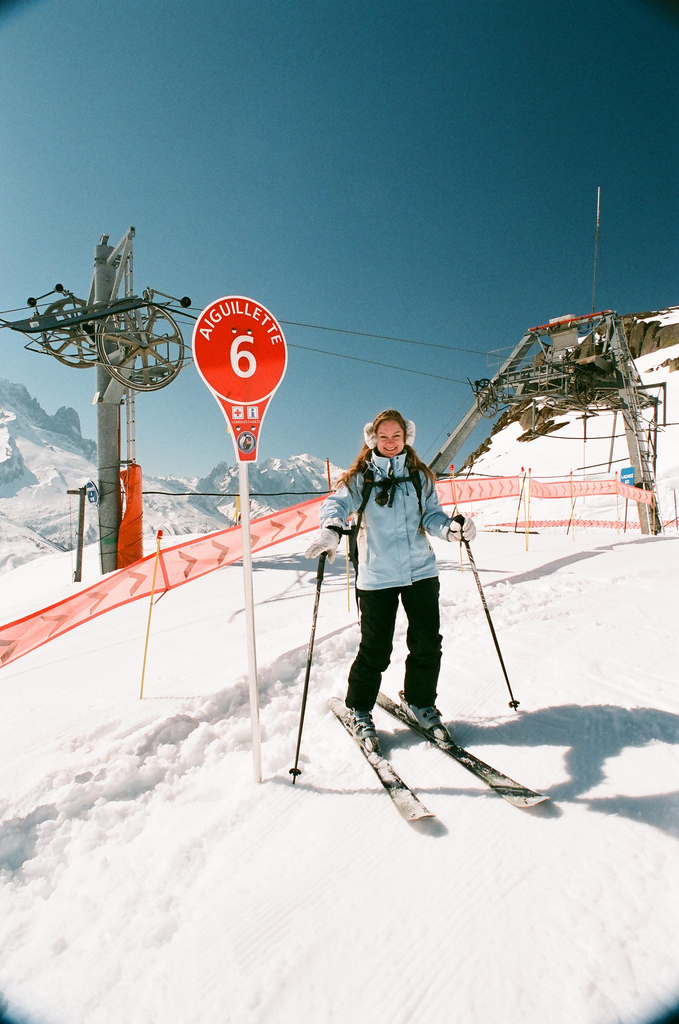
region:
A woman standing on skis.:
[281, 412, 545, 829]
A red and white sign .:
[191, 297, 287, 789]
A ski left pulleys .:
[13, 223, 185, 567]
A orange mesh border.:
[20, 493, 330, 658]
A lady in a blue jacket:
[316, 411, 458, 597]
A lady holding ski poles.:
[276, 411, 518, 790]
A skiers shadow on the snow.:
[387, 697, 677, 807]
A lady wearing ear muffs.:
[302, 407, 477, 732]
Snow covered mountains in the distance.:
[5, 378, 333, 570]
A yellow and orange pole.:
[135, 530, 165, 705]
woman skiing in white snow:
[292, 392, 548, 843]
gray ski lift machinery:
[23, 221, 184, 414]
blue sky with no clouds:
[108, 139, 158, 183]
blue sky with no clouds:
[483, 86, 535, 126]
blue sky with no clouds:
[368, 199, 422, 278]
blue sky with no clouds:
[273, 100, 329, 162]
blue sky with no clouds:
[370, 98, 441, 187]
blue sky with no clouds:
[219, 59, 267, 128]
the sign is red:
[182, 284, 297, 796]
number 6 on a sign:
[226, 318, 271, 390]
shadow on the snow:
[449, 687, 677, 838]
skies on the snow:
[324, 682, 556, 834]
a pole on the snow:
[33, 217, 219, 603]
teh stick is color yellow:
[126, 521, 173, 711]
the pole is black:
[452, 507, 529, 717]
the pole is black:
[272, 525, 341, 791]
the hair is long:
[322, 405, 451, 554]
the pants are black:
[348, 580, 448, 716]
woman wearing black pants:
[348, 582, 445, 690]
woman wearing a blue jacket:
[312, 458, 453, 580]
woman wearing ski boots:
[334, 696, 458, 750]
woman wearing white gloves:
[301, 528, 348, 563]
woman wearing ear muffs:
[356, 425, 378, 450]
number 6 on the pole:
[190, 286, 294, 407]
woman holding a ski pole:
[265, 532, 332, 806]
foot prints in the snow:
[136, 694, 238, 766]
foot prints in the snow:
[462, 567, 551, 631]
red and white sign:
[203, 288, 290, 492]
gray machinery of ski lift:
[43, 216, 186, 464]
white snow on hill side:
[140, 850, 197, 896]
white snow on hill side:
[381, 966, 426, 1004]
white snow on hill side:
[586, 598, 627, 634]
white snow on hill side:
[513, 577, 559, 617]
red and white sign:
[192, 297, 289, 458]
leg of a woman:
[347, 592, 387, 708]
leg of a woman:
[399, 580, 439, 704]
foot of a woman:
[405, 694, 437, 737]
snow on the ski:
[323, 697, 431, 822]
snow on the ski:
[362, 686, 548, 804]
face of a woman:
[370, 415, 402, 458]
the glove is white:
[309, 531, 339, 562]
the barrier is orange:
[0, 472, 656, 669]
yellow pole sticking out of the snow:
[133, 528, 164, 710]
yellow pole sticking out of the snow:
[319, 457, 334, 491]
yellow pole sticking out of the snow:
[340, 525, 352, 613]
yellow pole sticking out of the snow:
[445, 463, 460, 567]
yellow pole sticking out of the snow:
[516, 457, 531, 554]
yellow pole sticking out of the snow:
[560, 460, 571, 546]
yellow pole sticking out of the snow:
[610, 461, 626, 531]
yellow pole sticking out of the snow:
[228, 490, 238, 539]